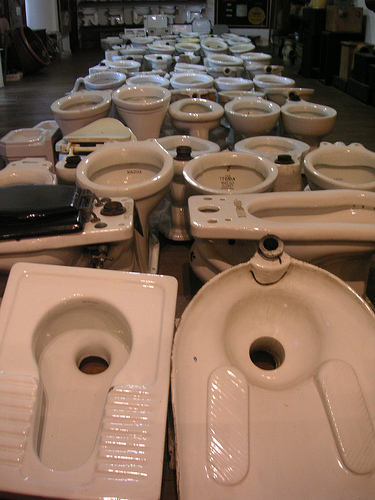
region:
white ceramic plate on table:
[5, 261, 168, 496]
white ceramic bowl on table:
[117, 83, 171, 138]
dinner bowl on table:
[208, 53, 240, 66]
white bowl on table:
[309, 142, 374, 195]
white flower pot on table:
[113, 84, 171, 139]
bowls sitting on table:
[10, 32, 373, 253]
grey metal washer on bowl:
[259, 231, 283, 258]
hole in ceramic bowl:
[245, 334, 290, 372]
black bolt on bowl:
[176, 146, 194, 161]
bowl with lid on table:
[58, 121, 134, 177]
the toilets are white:
[108, 165, 336, 492]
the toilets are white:
[129, 165, 251, 429]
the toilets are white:
[76, 218, 261, 464]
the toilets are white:
[137, 267, 282, 492]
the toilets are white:
[58, 176, 201, 360]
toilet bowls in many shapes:
[0, 8, 372, 497]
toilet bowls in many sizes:
[5, 10, 367, 498]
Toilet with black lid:
[0, 178, 135, 256]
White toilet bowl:
[175, 98, 223, 134]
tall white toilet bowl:
[114, 84, 174, 135]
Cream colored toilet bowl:
[261, 83, 314, 100]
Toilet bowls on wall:
[79, 6, 212, 29]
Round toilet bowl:
[75, 72, 123, 88]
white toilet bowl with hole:
[3, 259, 165, 499]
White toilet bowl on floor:
[5, 112, 54, 157]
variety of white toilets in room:
[170, 94, 216, 129]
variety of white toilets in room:
[6, 270, 170, 490]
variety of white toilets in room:
[189, 258, 373, 498]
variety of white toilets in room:
[98, 147, 164, 218]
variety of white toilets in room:
[194, 151, 273, 185]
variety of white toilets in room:
[312, 141, 374, 188]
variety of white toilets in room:
[283, 96, 331, 132]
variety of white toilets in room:
[62, 86, 103, 120]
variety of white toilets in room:
[128, 83, 163, 124]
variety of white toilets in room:
[219, 92, 275, 124]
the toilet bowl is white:
[126, 32, 297, 152]